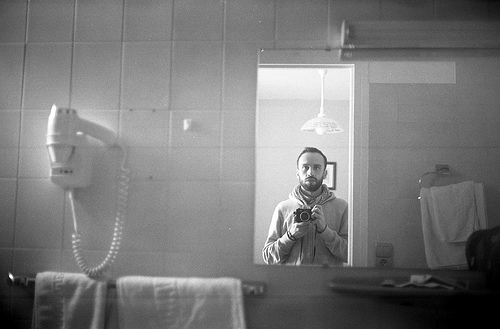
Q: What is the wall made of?
A: Tiles.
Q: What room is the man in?
A: Bathroom.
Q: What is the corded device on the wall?
A: A blow dryer.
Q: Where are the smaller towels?
A: On the towel ring.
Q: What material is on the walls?
A: Ceramic tiles.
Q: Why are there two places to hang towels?
A: One for towels, one for washcloths.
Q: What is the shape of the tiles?
A: Rectangle.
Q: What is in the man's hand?
A: A camera.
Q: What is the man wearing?
A: A hooded sweater.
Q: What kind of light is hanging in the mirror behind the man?
A: Pendant light.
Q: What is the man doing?
A: Taking a picture.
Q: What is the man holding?
A: A camera.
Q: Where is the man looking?
A: In a mirror.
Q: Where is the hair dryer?
A: On the wall.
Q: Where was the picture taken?
A: In a bathroom.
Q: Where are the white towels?
A: On the towel rack.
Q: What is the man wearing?
A: A hoodie.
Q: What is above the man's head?
A: A light fixture.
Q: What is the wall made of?
A: Tiles.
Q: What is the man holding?
A: A camera.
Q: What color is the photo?
A: Black and white.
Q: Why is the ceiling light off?
A: It is daytime.